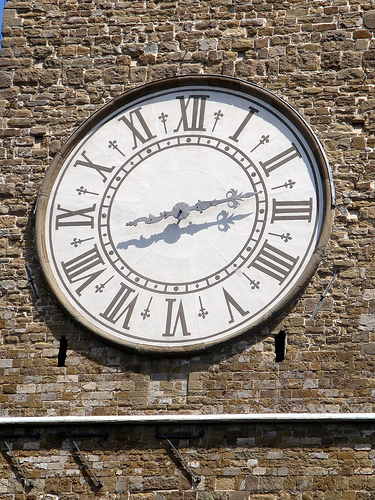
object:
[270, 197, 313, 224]
roman numeral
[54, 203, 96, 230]
roman numeral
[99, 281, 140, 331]
roman numeral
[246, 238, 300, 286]
roman numeral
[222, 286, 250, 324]
roman numeral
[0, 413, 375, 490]
shelf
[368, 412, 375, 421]
edge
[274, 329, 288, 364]
hole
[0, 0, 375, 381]
photo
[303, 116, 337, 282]
bracket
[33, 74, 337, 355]
clock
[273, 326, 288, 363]
spot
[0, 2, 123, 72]
building part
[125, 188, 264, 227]
hand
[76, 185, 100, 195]
decoration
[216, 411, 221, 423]
board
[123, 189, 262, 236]
clock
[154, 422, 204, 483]
metal bracket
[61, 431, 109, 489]
metal bracket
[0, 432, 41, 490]
metal bracket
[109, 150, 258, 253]
sky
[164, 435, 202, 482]
steel railing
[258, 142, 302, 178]
numeral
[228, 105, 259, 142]
numeral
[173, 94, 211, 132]
numeral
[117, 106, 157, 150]
numeral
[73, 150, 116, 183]
numeral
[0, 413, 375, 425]
ledge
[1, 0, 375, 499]
stone wall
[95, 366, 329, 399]
stone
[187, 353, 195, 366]
part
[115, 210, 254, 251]
hands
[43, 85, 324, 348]
clock face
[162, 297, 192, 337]
roman numerals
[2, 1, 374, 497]
brick building